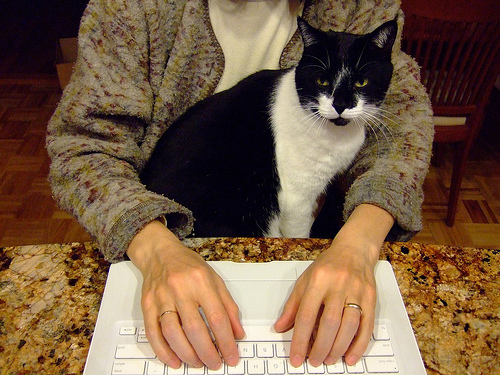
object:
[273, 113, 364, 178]
white chest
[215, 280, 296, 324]
touchpad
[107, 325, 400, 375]
keyboard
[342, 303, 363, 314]
ring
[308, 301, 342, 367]
finger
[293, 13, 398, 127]
head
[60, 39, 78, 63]
cardboard box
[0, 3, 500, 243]
floor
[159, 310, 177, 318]
ring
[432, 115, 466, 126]
seat cushion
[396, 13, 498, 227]
wood chair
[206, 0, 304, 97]
white shirt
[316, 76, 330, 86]
eyes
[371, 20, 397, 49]
ear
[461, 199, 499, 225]
tiles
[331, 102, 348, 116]
nose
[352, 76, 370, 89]
eye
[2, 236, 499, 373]
table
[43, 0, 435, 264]
housecoat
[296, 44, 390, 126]
face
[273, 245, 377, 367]
hand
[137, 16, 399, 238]
cat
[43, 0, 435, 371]
person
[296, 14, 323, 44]
ear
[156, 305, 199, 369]
finger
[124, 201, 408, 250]
lap